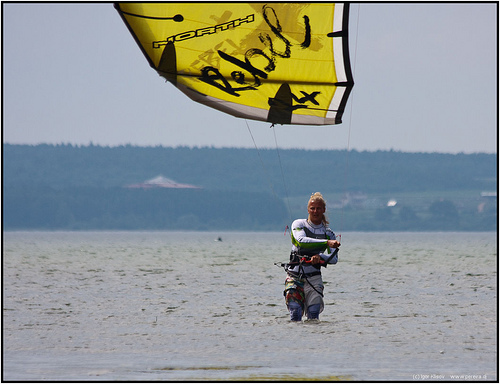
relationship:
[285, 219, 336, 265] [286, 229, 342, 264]
two hands on poles two hands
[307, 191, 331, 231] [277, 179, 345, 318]
hair on lady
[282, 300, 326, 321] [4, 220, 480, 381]
knees in water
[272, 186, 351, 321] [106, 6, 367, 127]
person flying kite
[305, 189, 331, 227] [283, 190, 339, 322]
head on kite flier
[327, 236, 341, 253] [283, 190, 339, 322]
hand on kite flier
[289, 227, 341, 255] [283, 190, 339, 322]
arm on kite flier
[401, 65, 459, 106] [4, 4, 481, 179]
white clouds in sky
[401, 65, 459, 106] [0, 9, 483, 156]
white clouds in sky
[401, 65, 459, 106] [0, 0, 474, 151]
white clouds in sky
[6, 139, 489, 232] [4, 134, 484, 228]
trees covering hill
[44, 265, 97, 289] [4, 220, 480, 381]
ripples on water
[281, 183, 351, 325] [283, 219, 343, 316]
woman wearing wet suit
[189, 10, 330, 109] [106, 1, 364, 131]
black letters on parasail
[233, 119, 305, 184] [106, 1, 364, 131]
lines on parasail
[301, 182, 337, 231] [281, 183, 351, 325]
hair on woman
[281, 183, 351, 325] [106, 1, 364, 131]
woman holding parasail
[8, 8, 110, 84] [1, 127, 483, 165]
haze over horizon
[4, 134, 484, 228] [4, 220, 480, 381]
hill overlooking water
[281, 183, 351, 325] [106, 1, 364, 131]
woman under parasail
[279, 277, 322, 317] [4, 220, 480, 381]
two legs in water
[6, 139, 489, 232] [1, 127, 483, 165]
trees in horizon